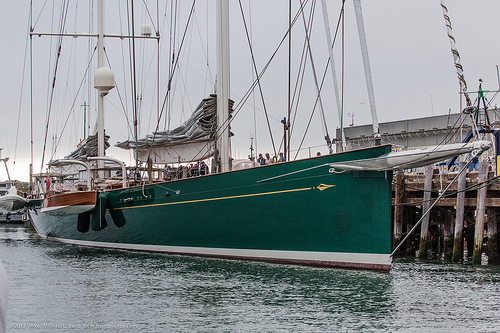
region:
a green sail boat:
[19, 135, 449, 277]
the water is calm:
[10, 278, 476, 331]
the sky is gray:
[367, 15, 445, 110]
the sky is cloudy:
[7, 20, 97, 112]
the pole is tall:
[205, 4, 251, 172]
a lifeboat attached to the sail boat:
[34, 191, 134, 214]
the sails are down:
[119, 92, 213, 146]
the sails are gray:
[66, 130, 94, 155]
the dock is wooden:
[411, 173, 498, 254]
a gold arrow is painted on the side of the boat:
[170, 180, 351, 197]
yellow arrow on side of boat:
[59, 176, 364, 226]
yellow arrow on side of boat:
[198, 147, 444, 260]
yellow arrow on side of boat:
[147, 153, 372, 278]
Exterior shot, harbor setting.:
[3, 10, 498, 330]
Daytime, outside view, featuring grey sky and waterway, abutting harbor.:
[6, 15, 498, 326]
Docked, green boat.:
[35, 3, 420, 286]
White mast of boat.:
[205, 3, 255, 172]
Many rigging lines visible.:
[25, 13, 385, 145]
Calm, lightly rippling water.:
[17, 273, 184, 313]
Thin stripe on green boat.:
[174, 180, 355, 213]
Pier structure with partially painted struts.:
[407, 172, 492, 262]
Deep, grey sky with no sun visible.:
[384, 37, 448, 104]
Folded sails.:
[72, 100, 217, 167]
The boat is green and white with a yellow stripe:
[18, 22, 443, 298]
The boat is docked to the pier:
[287, 100, 479, 290]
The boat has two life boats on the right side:
[0, 160, 167, 240]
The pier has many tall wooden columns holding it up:
[376, 153, 493, 263]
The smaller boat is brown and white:
[28, 184, 107, 214]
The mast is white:
[71, 15, 253, 187]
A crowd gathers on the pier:
[128, 127, 318, 188]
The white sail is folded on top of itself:
[132, 77, 220, 144]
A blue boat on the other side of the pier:
[427, 100, 494, 175]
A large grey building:
[325, 102, 491, 167]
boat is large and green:
[38, 132, 435, 312]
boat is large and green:
[27, 120, 464, 315]